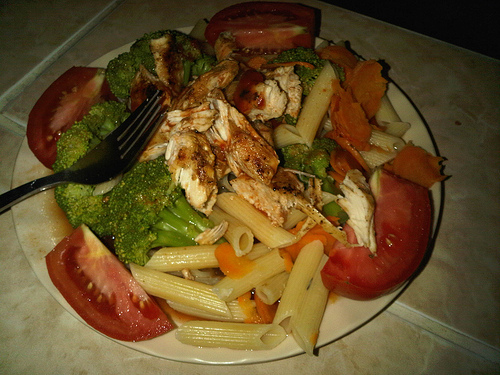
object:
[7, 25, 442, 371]
plate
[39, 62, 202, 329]
veggies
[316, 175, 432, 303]
tomato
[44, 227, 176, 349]
tomato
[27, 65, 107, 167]
tomato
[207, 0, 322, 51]
tomato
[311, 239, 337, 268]
ground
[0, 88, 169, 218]
silverware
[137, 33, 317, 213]
chicken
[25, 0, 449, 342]
tomato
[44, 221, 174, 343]
slice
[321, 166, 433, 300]
slice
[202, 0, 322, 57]
slice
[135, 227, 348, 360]
noodles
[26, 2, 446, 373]
meal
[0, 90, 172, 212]
fork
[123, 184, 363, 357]
pasta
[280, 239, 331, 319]
penne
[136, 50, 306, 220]
oven roasted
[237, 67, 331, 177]
tuna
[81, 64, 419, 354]
penne pasta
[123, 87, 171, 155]
prong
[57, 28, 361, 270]
broccoli